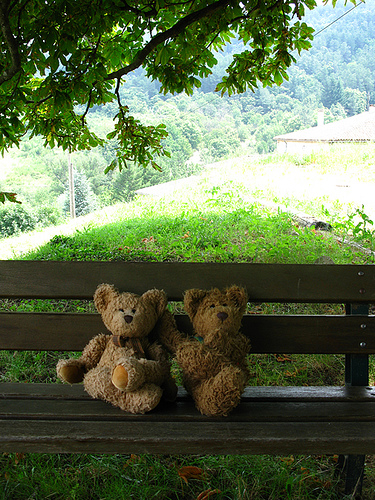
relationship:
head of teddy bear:
[93, 283, 169, 339] [55, 282, 170, 415]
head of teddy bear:
[182, 285, 247, 339] [178, 285, 250, 414]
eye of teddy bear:
[208, 301, 217, 310] [178, 285, 250, 414]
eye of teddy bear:
[221, 301, 229, 310] [178, 285, 250, 414]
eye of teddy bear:
[118, 305, 124, 313] [55, 282, 170, 415]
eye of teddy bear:
[130, 306, 139, 315] [55, 282, 170, 415]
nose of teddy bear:
[123, 317, 132, 325] [55, 282, 170, 415]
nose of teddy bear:
[216, 309, 227, 321] [178, 285, 250, 414]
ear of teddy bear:
[185, 289, 201, 317] [55, 282, 170, 415]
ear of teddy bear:
[228, 285, 247, 313] [178, 285, 250, 414]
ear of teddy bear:
[94, 284, 119, 313] [55, 282, 170, 415]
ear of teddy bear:
[143, 287, 165, 320] [55, 282, 170, 415]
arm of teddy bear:
[56, 334, 104, 385] [55, 282, 170, 415]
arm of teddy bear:
[111, 335, 172, 392] [55, 282, 170, 415]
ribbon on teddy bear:
[116, 335, 144, 357] [55, 282, 170, 415]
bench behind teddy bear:
[1, 259, 375, 496] [55, 282, 170, 415]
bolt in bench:
[360, 340, 364, 350] [1, 259, 375, 496]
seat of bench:
[1, 386, 372, 455] [1, 259, 375, 496]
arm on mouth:
[208, 332, 256, 365] [215, 326, 227, 332]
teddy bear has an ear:
[55, 282, 170, 415] [94, 284, 119, 313]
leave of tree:
[214, 80, 224, 92] [1, 1, 315, 172]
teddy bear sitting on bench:
[55, 282, 170, 415] [1, 259, 375, 496]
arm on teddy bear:
[159, 309, 193, 357] [55, 282, 170, 415]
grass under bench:
[2, 460, 335, 497] [1, 259, 375, 496]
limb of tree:
[103, 1, 231, 82] [1, 1, 315, 172]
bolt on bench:
[360, 326, 366, 331] [1, 259, 375, 496]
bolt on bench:
[359, 270, 365, 278] [1, 259, 375, 496]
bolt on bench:
[360, 287, 364, 296] [1, 259, 375, 496]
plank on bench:
[2, 262, 372, 304] [1, 259, 375, 496]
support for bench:
[344, 307, 369, 478] [1, 259, 375, 496]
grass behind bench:
[2, 207, 375, 499] [1, 259, 375, 496]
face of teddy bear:
[195, 295, 243, 338] [55, 282, 170, 415]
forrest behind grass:
[2, 21, 372, 229] [2, 207, 375, 499]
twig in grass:
[350, 475, 359, 499] [2, 207, 375, 499]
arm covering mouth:
[208, 332, 256, 365] [215, 326, 227, 332]